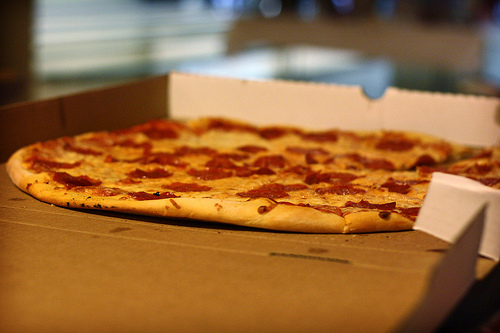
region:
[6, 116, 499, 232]
a pizza pie in the pizza box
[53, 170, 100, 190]
pepperoni on the pizza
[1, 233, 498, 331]
the open pizza box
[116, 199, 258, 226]
the light brown pizza crust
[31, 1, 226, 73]
an appliance reflecting the light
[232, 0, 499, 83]
a wooden kitchen counter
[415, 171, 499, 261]
a paper bill for the cost of the pizza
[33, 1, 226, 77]
a window with light shinning through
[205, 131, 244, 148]
mozzarella cheese on the pizza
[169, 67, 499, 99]
the perforated top of the pizza box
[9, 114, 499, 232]
a pizza in a card board box.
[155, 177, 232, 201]
a pepperoni on a pizza.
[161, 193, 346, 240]
a section of pizza crust.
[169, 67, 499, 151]
a pizza box with a pizza.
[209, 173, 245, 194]
a section of cheese on a pizza.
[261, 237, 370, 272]
a hole in a pizza box.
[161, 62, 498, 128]
a section of card board box.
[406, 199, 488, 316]
a cardboard flap.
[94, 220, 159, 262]
a small pool of grease.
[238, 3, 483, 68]
a section of a wall.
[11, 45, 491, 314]
Pizza in the box.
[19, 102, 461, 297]
Box with pizza in it.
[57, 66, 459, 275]
Pepperoni on the pizza.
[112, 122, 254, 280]
Crust on the pizza.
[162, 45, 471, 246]
Cardboard box with pizza.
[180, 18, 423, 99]
Blurry scene in the background.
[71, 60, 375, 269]
Cheese on the pizza.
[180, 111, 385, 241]
Red pepperonis on the pizza.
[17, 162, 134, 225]
Seasoning on the crust.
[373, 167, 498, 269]
Edge of the box.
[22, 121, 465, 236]
A large pepperoni pizza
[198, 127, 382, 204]
There are pepperoni's on the pizza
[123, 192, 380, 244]
The pizza has thin crust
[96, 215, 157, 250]
Grease from the pizza on the box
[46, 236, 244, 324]
Cardboard pizza box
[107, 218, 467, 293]
Seam in the cardboard box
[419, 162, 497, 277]
Fold on the pizza box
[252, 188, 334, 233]
The crust is somewhat burnt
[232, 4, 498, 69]
The background is blurry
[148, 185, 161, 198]
Spices on top of the pizza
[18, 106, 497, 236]
a pepperoni pizza pie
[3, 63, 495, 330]
a brown cardboard pizza box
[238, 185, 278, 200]
a slice of pepperoni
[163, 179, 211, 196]
a slice of pepperoni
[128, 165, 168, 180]
a slice of pepperoni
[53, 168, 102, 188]
a slice of pepperoni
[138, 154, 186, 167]
a slice of pepperoni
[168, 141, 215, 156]
a slice of pepperoni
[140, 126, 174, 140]
a slice of pepperoni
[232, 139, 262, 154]
a slice of pepperoni